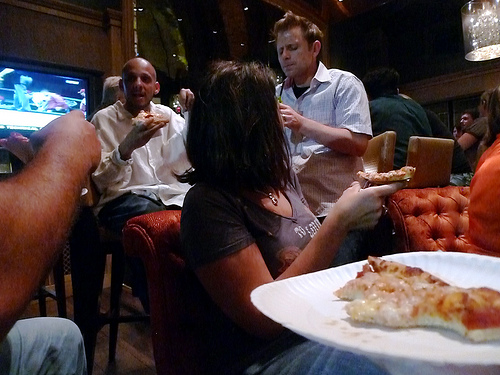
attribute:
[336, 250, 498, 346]
pizza — sliced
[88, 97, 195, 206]
shirt — white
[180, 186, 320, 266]
shirt — grey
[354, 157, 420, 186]
pizza — sliced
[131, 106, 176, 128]
pizza — sliced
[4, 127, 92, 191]
pizza — sliced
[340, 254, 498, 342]
pizza — half-eaten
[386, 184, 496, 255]
chair back — orange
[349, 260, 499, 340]
pizza — cheese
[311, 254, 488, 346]
platter — white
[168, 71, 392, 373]
hair — brown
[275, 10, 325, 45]
hair — brown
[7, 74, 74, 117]
match — boxing